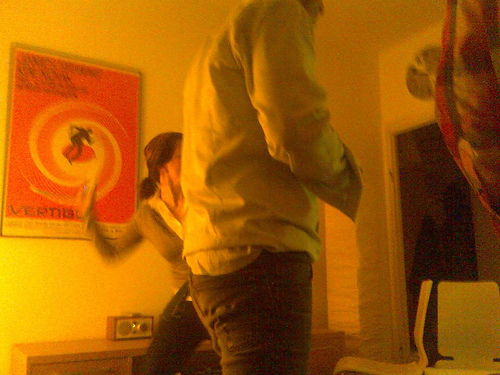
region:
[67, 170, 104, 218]
The woman is holding a Wii remote.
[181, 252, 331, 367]
The man is wearing blue jeans.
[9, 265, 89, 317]
The wall is yellow.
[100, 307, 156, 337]
The radio is small.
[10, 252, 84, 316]
The wall is smooth.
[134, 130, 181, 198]
The woman has brown hair.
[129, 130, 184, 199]
The woman's hair is in a pony tail.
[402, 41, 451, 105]
The clock is on the wall.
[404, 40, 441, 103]
The clock is silver.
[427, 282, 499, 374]
The chair in the background is white.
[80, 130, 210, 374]
an active video gamer in the room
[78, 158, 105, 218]
Wii controller in the woman's hand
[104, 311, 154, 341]
small electronic device on the shelf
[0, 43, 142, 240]
a poster on the wall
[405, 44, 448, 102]
a clock mounted high on the wall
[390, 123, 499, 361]
an open doorway in the room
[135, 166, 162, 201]
hair in a pony tail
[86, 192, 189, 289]
a gray sweater on a woman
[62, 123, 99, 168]
an animal figure on the wall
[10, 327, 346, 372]
a credenza of blond wood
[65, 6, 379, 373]
two people playing a video game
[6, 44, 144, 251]
poster hanging on the wall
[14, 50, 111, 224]
black text on red background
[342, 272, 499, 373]
two white unoccupied chairs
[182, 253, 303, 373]
blue jeans man is wearing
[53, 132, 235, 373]
woman swinging the game controller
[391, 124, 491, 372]
doorway with white frame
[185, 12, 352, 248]
long sleeve shirt the man is wearing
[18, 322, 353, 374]
bench behind the woman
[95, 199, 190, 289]
gray shirt the woman is wearing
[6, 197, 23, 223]
The letter is black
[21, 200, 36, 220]
The letter is black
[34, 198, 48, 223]
The letter is black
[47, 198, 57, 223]
The letter is black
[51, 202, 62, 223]
The letter is black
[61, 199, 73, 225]
The letter is black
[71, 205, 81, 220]
The letter is black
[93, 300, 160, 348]
Old style wooden radio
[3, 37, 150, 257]
Poster is hanging on wall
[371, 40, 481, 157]
Clock hanging above door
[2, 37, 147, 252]
Picture on the wall.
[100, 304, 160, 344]
Radio on the table.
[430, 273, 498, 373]
White chair in the room.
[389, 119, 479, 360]
door in the room.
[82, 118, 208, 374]
Woman behind the man.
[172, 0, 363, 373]
man in front of the woman.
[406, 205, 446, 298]
coat on the hook.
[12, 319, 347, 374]
Table against the wall.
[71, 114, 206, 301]
Gray sweater on the woman.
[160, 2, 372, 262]
Long sleeve shirt on the man.